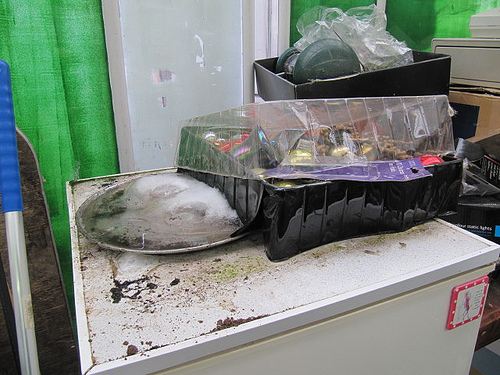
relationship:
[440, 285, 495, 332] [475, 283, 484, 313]
magnet with writing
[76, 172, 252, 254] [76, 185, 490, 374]
mold on table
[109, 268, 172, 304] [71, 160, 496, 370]
dirt on white surface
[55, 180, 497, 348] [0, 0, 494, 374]
freezer in room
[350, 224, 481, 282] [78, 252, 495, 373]
edge of a fridge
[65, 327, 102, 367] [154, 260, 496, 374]
part of a board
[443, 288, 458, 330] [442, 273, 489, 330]
edge of a board